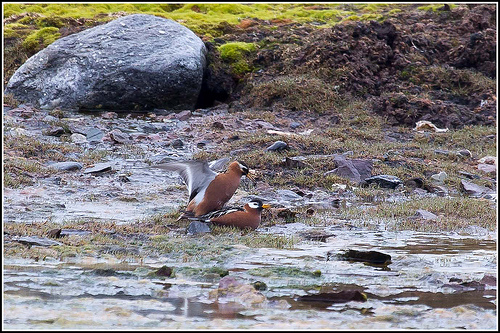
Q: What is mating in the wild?
A: Two birds.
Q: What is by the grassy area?
A: Gray rock with white spots.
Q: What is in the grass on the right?
A: Sharp rocks.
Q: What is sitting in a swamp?
A: Two brown and white birds.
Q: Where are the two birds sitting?
A: On the ground.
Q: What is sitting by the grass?
A: A big greyish rock.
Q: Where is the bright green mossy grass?
A: By the rock.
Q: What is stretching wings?
A: The bird.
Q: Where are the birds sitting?
A: The birds are sitting on a beach.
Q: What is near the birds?
A: There are rocks near the birds.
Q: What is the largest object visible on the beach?
A: There is a very large rock on the beach.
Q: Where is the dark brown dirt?
A: The dark brown dirt is gathered in a mound.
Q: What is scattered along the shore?
A: Groups of rocks are scattered along the shore.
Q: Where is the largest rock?
A: In the upper left corner of the image.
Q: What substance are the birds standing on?
A: Mud.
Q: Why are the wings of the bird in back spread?
A: It is flying a little.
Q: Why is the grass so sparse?
A: The soil is too cold and wet for it to thrive.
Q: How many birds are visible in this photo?
A: Two.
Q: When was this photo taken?
A: Outside, during the daytime.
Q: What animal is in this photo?
A: Birds.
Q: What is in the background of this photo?
A: A large rock.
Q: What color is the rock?
A: Gray.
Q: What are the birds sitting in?
A: Mud.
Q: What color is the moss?
A: Green.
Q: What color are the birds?
A: Brown and gray.